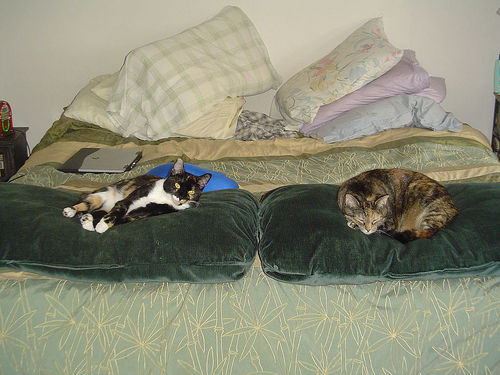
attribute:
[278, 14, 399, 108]
case — floral pillow 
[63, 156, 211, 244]
kitty — white 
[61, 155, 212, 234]
cat — dark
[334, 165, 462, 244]
cat — light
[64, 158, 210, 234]
calico cat — calico , looking, black, white, laying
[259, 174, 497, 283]
pillow — green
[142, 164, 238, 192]
pillow — blue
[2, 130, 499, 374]
comforter — floral design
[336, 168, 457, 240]
cat — sleeping, laying, laying down, black, brown 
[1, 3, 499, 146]
wall — lavender , white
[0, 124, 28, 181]
table — bed side 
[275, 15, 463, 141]
pillows — stack  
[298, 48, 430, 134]
pillow — purple